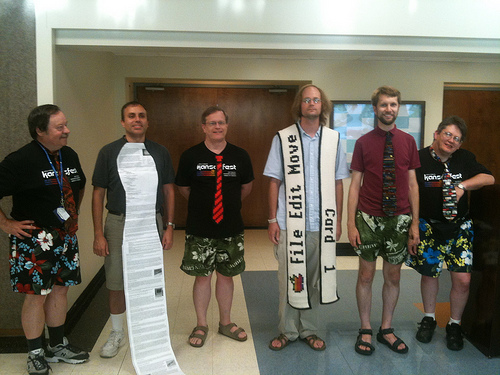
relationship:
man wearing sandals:
[175, 103, 260, 364] [181, 318, 249, 355]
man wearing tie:
[175, 103, 260, 364] [212, 151, 240, 223]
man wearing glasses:
[263, 82, 351, 352] [302, 94, 321, 104]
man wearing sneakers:
[98, 99, 185, 374] [95, 322, 146, 372]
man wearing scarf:
[271, 63, 343, 323] [270, 121, 339, 202]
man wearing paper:
[98, 99, 185, 374] [117, 152, 173, 336]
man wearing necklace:
[27, 95, 89, 216] [40, 148, 72, 198]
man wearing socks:
[98, 99, 185, 374] [105, 305, 128, 331]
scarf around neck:
[275, 121, 341, 310] [296, 113, 339, 141]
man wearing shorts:
[27, 95, 89, 216] [11, 229, 90, 295]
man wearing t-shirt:
[175, 103, 260, 364] [179, 149, 263, 237]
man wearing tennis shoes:
[27, 95, 89, 216] [12, 344, 85, 375]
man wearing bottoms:
[175, 103, 260, 364] [180, 238, 282, 276]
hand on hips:
[3, 212, 32, 237] [3, 217, 93, 243]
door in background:
[166, 93, 284, 187] [54, 41, 494, 140]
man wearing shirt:
[357, 86, 439, 279] [358, 130, 417, 205]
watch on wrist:
[261, 213, 281, 227] [265, 212, 284, 226]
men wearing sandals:
[16, 101, 476, 319] [181, 318, 249, 355]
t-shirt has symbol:
[179, 149, 263, 237] [209, 161, 217, 181]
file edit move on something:
[280, 131, 311, 278] [279, 138, 342, 301]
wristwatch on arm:
[155, 216, 182, 230] [155, 185, 179, 234]